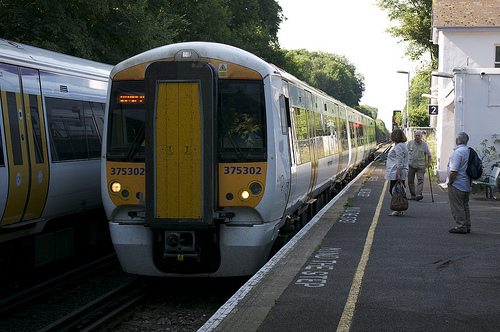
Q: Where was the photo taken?
A: At a train station.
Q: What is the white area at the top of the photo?
A: The sky.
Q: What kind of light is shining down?
A: Sunlight.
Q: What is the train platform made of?
A: Asphalt.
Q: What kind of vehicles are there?
A: Trains.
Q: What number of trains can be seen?
A: Two.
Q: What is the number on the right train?
A: 375302.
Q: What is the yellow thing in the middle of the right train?
A: A door.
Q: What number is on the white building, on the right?
A: 2.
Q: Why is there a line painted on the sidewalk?
A: Safety.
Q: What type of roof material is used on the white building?
A: Shingles.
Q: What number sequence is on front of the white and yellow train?
A: 375302.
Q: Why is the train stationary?
A: To allow people to exit and enter the train.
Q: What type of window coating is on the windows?
A: Tint.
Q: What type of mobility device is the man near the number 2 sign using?
A: A walking cane.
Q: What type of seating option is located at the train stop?
A: A bench.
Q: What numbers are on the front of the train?
A: 375302.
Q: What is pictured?
A: A train.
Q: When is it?
A: Day time.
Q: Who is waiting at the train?
A: Passengers.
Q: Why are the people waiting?
A: To get on the train.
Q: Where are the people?
A: Standing beside the train.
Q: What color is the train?
A: White and yellow.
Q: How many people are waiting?
A: 3.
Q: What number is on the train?
A: 375302.